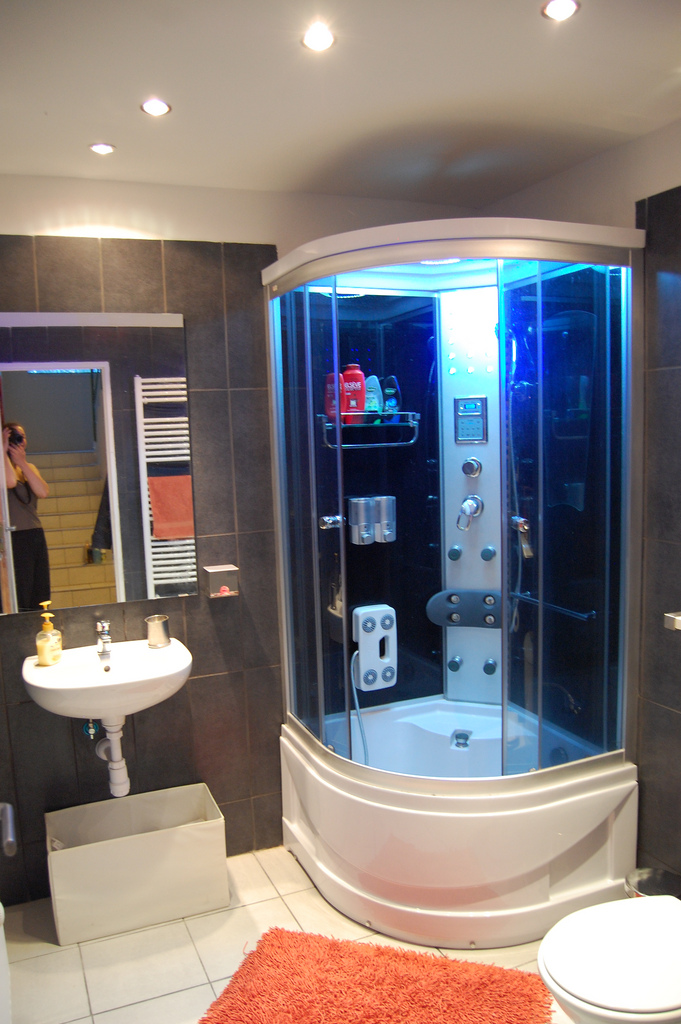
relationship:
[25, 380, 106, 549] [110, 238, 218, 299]
mirror fixed to wall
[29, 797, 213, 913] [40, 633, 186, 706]
tub under sink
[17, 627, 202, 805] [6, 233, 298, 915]
sink mounted to wall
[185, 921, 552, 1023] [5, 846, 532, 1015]
rug on floor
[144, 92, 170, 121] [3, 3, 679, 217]
light on ceiling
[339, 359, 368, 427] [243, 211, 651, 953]
bottle in shoer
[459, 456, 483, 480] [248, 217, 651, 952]
knob in shower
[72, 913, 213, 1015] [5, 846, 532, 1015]
tile on floor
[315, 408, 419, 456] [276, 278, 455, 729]
shelf on wall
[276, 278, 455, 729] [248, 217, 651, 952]
wall on shower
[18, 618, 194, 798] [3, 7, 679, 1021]
sink in bathroom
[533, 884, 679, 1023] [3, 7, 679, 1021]
toilet in bathroom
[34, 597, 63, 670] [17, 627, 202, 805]
bottle on sink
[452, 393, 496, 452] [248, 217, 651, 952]
controls on shower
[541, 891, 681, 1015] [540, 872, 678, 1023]
lid on toilet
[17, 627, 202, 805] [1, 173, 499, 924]
sink against wall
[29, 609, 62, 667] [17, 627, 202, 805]
bottle on sink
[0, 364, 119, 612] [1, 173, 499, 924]
mirror on wall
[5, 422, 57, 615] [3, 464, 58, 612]
woman in dress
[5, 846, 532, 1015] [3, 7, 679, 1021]
floor in bathroom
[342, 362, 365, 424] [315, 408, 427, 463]
bottle on shelf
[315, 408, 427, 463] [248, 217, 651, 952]
shelf in shower